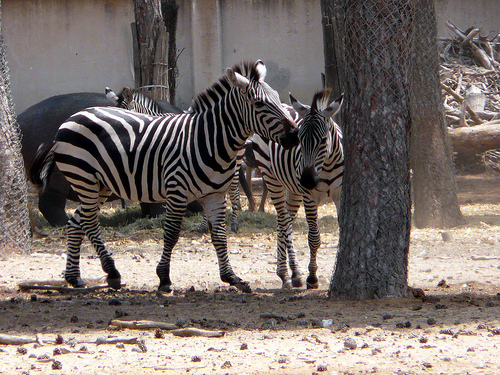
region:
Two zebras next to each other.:
[26, 57, 346, 308]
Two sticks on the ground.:
[111, 313, 226, 343]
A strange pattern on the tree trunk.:
[341, 98, 411, 302]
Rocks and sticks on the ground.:
[9, 323, 118, 373]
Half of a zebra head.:
[106, 88, 161, 110]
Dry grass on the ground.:
[112, 218, 160, 240]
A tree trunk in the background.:
[123, 3, 178, 96]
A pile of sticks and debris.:
[448, 29, 499, 121]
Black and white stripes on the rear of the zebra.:
[56, 112, 154, 180]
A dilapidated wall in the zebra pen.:
[186, 6, 311, 53]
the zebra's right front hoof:
[154, 259, 179, 294]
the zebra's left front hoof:
[216, 263, 256, 298]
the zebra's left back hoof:
[61, 261, 87, 288]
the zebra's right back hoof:
[101, 258, 125, 288]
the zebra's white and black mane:
[185, 64, 258, 115]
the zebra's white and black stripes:
[63, 118, 198, 177]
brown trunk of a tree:
[333, 38, 413, 300]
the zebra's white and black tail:
[29, 138, 58, 193]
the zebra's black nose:
[297, 166, 319, 193]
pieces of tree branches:
[440, 27, 497, 151]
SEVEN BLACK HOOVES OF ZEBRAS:
[62, 258, 327, 293]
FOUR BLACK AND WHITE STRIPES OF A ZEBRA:
[67, 114, 109, 171]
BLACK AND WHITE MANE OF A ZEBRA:
[179, 62, 254, 110]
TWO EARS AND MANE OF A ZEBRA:
[286, 88, 348, 120]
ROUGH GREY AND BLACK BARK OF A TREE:
[342, 128, 412, 193]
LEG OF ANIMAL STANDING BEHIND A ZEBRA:
[29, 175, 69, 227]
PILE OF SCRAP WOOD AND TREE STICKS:
[448, 46, 493, 117]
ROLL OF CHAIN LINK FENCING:
[1, 91, 28, 263]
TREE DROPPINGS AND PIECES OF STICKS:
[46, 311, 217, 373]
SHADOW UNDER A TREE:
[15, 289, 498, 326]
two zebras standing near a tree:
[38, 61, 340, 295]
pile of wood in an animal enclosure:
[436, 22, 499, 178]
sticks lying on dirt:
[108, 318, 227, 336]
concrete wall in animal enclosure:
[0, 0, 495, 116]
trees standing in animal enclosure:
[331, 3, 467, 298]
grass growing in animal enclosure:
[27, 204, 332, 248]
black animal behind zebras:
[20, 89, 181, 226]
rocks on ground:
[0, 295, 494, 371]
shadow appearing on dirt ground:
[0, 294, 487, 329]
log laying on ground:
[447, 118, 498, 155]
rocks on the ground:
[303, 308, 375, 359]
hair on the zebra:
[200, 84, 227, 101]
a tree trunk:
[341, 40, 410, 295]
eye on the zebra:
[241, 97, 264, 109]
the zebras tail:
[34, 146, 59, 178]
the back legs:
[61, 215, 127, 295]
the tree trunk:
[415, 129, 460, 229]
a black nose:
[302, 161, 317, 187]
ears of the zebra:
[287, 93, 311, 113]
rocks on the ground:
[321, 325, 399, 360]